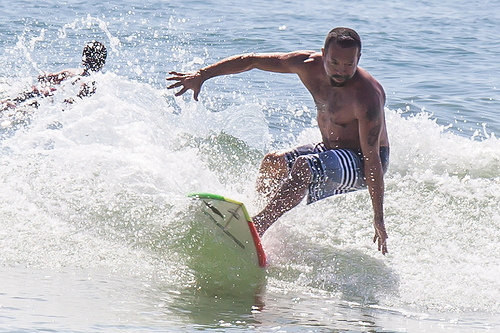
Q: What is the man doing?
A: Surfing.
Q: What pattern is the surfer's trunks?
A: Striped.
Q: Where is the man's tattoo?
A: On his arm.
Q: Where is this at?
A: In the ocean.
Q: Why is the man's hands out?
A: For balance.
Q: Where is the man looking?
A: At the water.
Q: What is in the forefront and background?
A: Water.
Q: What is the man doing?
A: Surfing.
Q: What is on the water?
A: A shadow.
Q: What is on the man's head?
A: Hair.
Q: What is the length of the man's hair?
A: Short.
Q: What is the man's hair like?
A: Dark.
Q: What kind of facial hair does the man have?
A: A mustache.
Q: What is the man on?
A: A surfboard.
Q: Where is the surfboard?
A: In water.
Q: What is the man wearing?
A: Shorts.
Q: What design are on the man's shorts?
A: Striped.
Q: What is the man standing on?
A: Surfboard.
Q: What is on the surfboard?
A: A man.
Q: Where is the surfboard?
A: The water.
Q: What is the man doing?
A: Surfing.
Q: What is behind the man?
A: Second surfer.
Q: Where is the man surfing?
A: The ocean.